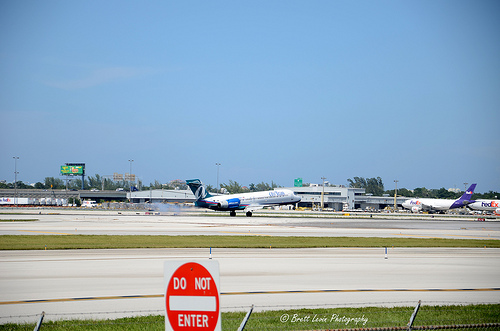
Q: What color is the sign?
A: Red and white.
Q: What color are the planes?
A: White.